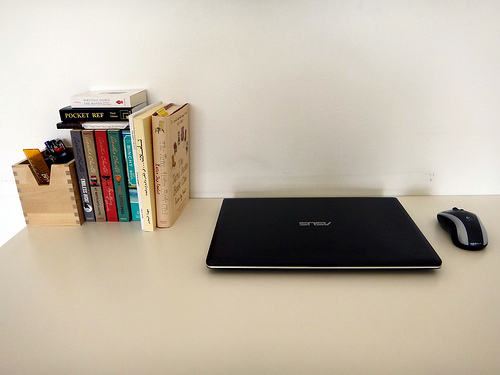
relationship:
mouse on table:
[437, 207, 489, 249] [2, 198, 498, 372]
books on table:
[57, 91, 193, 231] [2, 198, 498, 372]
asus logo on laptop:
[300, 220, 333, 226] [205, 198, 444, 272]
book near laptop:
[153, 104, 192, 229] [205, 198, 444, 272]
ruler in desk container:
[25, 149, 50, 182] [11, 162, 81, 223]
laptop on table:
[205, 198, 444, 272] [2, 198, 498, 372]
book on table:
[153, 104, 192, 229] [2, 198, 498, 372]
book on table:
[135, 116, 158, 230] [2, 198, 498, 372]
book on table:
[72, 128, 95, 222] [2, 198, 498, 372]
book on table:
[81, 131, 107, 224] [2, 198, 498, 372]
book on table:
[60, 106, 134, 122] [2, 198, 498, 372]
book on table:
[72, 88, 150, 108] [2, 198, 498, 372]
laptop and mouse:
[205, 198, 444, 272] [437, 207, 489, 249]